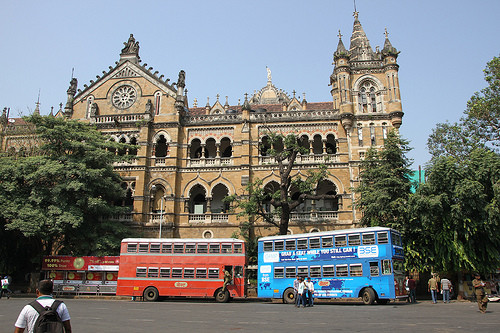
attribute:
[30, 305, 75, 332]
backpack — black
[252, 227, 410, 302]
bus — blue, double decked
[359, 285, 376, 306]
tire — black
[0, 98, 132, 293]
tree — green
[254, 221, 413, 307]
bus — blue, double decker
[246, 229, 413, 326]
bus — wheel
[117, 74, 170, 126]
window — round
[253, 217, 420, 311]
bus — window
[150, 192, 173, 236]
post — lamp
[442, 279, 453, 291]
shirt — gray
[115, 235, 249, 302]
bus — red, blue